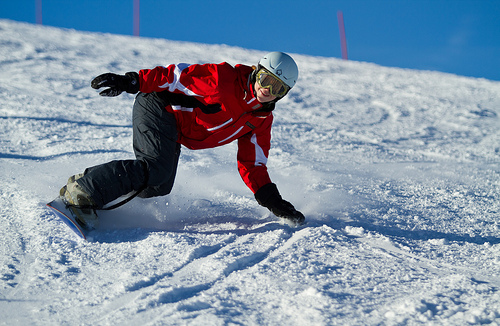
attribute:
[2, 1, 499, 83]
sky — blue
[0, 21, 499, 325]
snow — white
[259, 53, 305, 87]
helmet — white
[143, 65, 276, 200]
jacket — red, white, red black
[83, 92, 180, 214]
trouser — black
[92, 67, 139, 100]
glove — black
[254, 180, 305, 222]
glove — black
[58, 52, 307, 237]
woman — snowboarding, smiling, balancing, going down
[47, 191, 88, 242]
snowboard — blue, white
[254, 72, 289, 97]
goggles — yellow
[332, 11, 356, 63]
pole — red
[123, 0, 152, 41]
pole — red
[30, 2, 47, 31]
pole — red, snow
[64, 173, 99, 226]
shoes — brown, tan, gray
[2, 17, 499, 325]
ground — covered